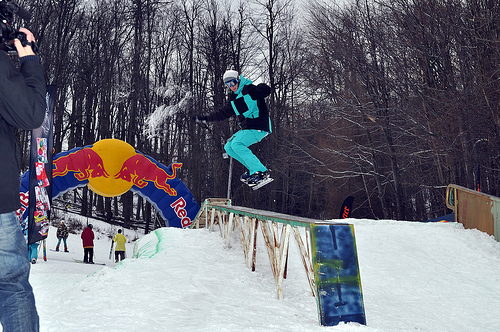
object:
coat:
[81, 226, 95, 248]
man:
[0, 0, 53, 330]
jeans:
[0, 212, 42, 329]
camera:
[0, 0, 41, 55]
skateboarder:
[213, 197, 333, 236]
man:
[192, 69, 279, 190]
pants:
[227, 125, 273, 195]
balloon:
[45, 147, 205, 207]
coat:
[111, 234, 127, 252]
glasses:
[221, 78, 238, 90]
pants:
[81, 247, 94, 263]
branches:
[286, 117, 401, 183]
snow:
[436, 283, 498, 329]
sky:
[258, 0, 378, 51]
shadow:
[249, 176, 280, 191]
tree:
[132, 22, 154, 157]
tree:
[145, 22, 173, 150]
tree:
[175, 22, 187, 173]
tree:
[179, 33, 201, 187]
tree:
[194, 27, 220, 194]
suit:
[199, 71, 278, 174]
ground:
[34, 225, 313, 330]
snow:
[186, 291, 231, 327]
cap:
[220, 70, 243, 86]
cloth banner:
[25, 85, 58, 246]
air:
[214, 188, 297, 217]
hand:
[13, 26, 38, 58]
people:
[55, 220, 67, 255]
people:
[80, 223, 95, 262]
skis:
[108, 237, 112, 262]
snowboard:
[214, 175, 287, 193]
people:
[111, 228, 127, 262]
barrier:
[189, 196, 368, 329]